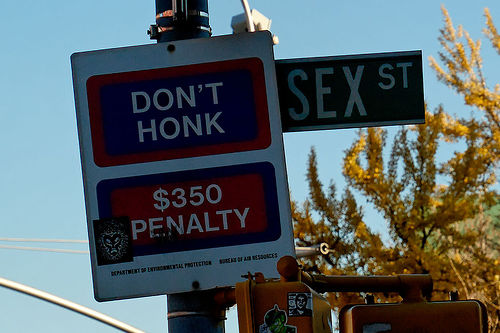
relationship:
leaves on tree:
[284, 0, 500, 333] [279, 8, 495, 328]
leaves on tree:
[284, 0, 500, 333] [322, 128, 499, 288]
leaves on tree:
[349, 206, 366, 235] [296, 127, 498, 322]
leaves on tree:
[284, 0, 500, 333] [296, 127, 498, 322]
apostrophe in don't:
[196, 82, 203, 95] [117, 74, 233, 114]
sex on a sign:
[281, 64, 371, 122] [278, 45, 432, 139]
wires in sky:
[2, 219, 92, 271] [6, 4, 498, 333]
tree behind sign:
[239, 9, 499, 332] [277, 49, 421, 124]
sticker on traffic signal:
[257, 303, 299, 333] [223, 250, 492, 331]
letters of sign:
[122, 209, 251, 238] [73, 37, 328, 284]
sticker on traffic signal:
[257, 305, 293, 332] [239, 276, 311, 332]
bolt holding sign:
[183, 278, 206, 289] [64, 27, 296, 296]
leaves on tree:
[284, 0, 500, 333] [298, 67, 493, 309]